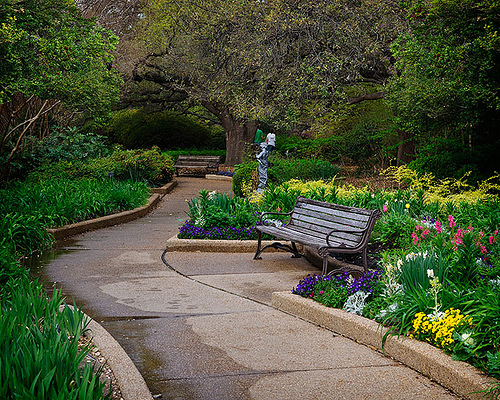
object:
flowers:
[399, 307, 481, 349]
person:
[265, 127, 275, 150]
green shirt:
[252, 126, 264, 144]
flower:
[380, 201, 391, 213]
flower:
[400, 197, 412, 213]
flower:
[445, 211, 455, 221]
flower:
[421, 225, 430, 235]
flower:
[422, 265, 434, 278]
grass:
[0, 130, 493, 395]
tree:
[1, 1, 122, 182]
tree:
[394, 2, 499, 176]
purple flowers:
[293, 267, 383, 295]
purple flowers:
[211, 169, 235, 178]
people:
[251, 124, 268, 158]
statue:
[254, 140, 270, 194]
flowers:
[173, 189, 242, 248]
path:
[32, 156, 496, 396]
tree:
[112, 2, 400, 169]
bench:
[252, 194, 380, 285]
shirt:
[264, 132, 276, 146]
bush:
[22, 123, 110, 166]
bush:
[231, 155, 338, 194]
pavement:
[43, 169, 176, 263]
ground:
[58, 223, 205, 398]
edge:
[92, 319, 154, 390]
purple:
[352, 268, 370, 290]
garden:
[359, 224, 491, 358]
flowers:
[380, 246, 422, 301]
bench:
[172, 152, 224, 178]